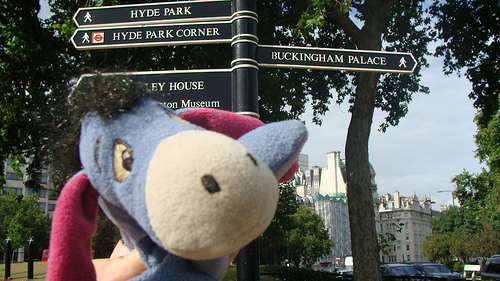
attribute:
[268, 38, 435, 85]
sign — pointing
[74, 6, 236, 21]
sign — pointing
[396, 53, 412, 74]
emblem — person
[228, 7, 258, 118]
stripes — white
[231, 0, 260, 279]
pole — black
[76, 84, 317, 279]
doll — stuffed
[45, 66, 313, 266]
toy — stuffed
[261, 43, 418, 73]
street sign —  street's,  Buckingham palace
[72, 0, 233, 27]
street sign —  street's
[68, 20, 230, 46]
street sign —  street's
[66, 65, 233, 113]
street sign —  street's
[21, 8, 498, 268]
england — of London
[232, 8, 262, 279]
pole — metal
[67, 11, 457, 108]
signs — metal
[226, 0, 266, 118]
pole — black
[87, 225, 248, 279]
hand — holding up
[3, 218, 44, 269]
poles —  two,  black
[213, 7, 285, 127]
pole — metal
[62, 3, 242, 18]
sign — person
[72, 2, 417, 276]
street sign — stacked up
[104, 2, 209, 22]
hyde park — a  sign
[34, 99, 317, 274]
animal — stuffed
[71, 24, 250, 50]
sign —  Hyde Park Corner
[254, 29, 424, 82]
sign —  Buckingham Palace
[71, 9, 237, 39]
sign — pointing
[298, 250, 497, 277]
park — grassy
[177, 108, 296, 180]
ears — pink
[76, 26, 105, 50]
emblem — person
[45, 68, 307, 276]
puppet —  eeyore